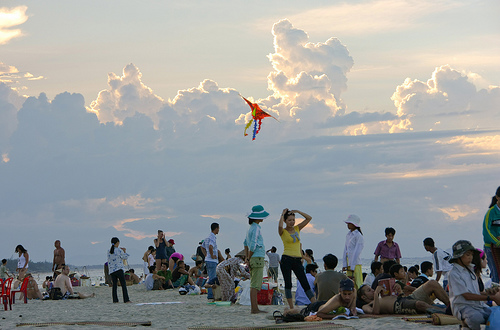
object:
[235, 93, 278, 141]
kite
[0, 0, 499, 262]
sky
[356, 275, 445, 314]
guy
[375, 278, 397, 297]
book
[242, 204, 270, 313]
girl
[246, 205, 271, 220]
hat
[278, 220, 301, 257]
teeshirt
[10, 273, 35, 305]
chairs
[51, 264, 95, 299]
man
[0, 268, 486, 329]
sand